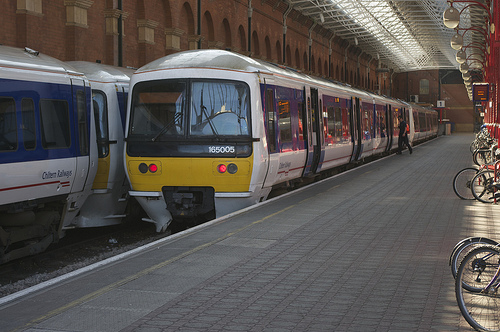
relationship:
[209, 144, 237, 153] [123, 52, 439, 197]
numbers in front of train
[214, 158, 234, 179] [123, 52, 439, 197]
light on train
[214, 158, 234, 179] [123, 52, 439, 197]
light in front of train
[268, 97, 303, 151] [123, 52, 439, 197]
window on train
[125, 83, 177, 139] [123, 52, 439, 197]
window on train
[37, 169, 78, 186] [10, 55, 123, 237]
letters on side of train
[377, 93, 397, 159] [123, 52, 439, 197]
doors on side of train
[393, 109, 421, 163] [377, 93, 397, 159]
person walking through doors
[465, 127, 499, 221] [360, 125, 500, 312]
bikes parked on platform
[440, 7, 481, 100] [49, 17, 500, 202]
skylights hanging in station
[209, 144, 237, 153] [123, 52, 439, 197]
numbers on train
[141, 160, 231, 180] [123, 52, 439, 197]
lights in front of train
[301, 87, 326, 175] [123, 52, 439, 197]
door on side of train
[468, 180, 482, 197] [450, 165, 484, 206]
spokes on tire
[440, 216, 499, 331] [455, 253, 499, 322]
bicycle has wheel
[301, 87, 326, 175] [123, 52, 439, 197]
door on train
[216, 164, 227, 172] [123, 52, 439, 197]
lights on train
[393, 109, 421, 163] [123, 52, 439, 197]
person walking on train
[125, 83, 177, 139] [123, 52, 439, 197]
window in front of train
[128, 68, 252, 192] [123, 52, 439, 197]
front of train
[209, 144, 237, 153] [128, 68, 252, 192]
numbers on front